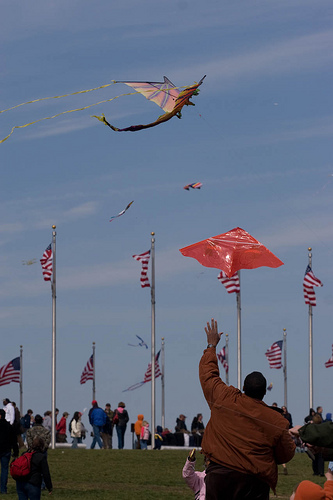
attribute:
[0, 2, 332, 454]
sky — blue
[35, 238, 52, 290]
flag — American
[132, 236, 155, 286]
flag — american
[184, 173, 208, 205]
kite — dragon kite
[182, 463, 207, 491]
jacket — pink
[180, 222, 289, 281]
kite — red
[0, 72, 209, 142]
kite — large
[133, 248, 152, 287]
flag — american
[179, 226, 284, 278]
kite — small, plastic, red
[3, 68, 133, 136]
ribbons — yellow, hanging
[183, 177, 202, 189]
kite — rainbow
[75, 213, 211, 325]
waving flag — american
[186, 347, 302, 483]
jacket — brown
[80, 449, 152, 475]
grass — green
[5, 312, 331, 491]
people — watching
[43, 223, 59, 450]
flag pole — tall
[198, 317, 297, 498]
man — large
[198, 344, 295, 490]
jacket — brown